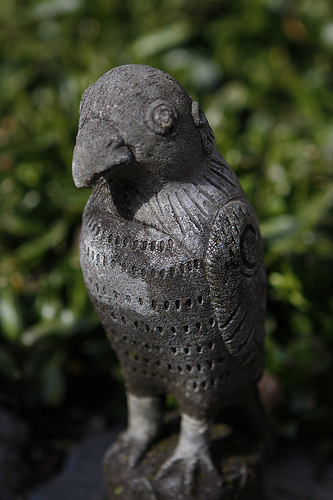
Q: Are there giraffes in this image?
A: No, there are no giraffes.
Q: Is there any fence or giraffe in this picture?
A: No, there are no giraffes or fences.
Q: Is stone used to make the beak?
A: Yes, the beak is made of stone.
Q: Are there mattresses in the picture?
A: No, there are no mattresses.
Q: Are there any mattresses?
A: No, there are no mattresses.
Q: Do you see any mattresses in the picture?
A: No, there are no mattresses.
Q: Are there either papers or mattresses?
A: No, there are no mattresses or papers.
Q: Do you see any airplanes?
A: No, there are no airplanes.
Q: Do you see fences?
A: No, there are no fences.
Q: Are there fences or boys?
A: No, there are no fences or boys.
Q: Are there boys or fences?
A: No, there are no fences or boys.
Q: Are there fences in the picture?
A: No, there are no fences.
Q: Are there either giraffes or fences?
A: No, there are no fences or giraffes.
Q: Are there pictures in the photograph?
A: No, there are no pictures.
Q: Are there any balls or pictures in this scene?
A: No, there are no pictures or balls.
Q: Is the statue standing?
A: Yes, the statue is standing.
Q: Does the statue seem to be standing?
A: Yes, the statue is standing.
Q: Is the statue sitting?
A: No, the statue is standing.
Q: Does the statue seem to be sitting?
A: No, the statue is standing.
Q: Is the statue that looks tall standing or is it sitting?
A: The statue is standing.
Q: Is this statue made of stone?
A: Yes, the statue is made of stone.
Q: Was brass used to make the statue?
A: No, the statue is made of stone.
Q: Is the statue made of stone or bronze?
A: The statue is made of stone.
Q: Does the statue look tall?
A: Yes, the statue is tall.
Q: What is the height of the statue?
A: The statue is tall.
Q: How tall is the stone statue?
A: The statue is tall.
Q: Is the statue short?
A: No, the statue is tall.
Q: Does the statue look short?
A: No, the statue is tall.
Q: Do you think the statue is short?
A: No, the statue is tall.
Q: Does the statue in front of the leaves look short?
A: No, the statue is tall.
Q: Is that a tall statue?
A: Yes, that is a tall statue.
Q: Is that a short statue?
A: No, that is a tall statue.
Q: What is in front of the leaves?
A: The statue is in front of the leaves.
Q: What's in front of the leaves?
A: The statue is in front of the leaves.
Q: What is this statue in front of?
A: The statue is in front of the leaves.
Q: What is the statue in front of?
A: The statue is in front of the leaves.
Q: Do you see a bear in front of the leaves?
A: No, there is a statue in front of the leaves.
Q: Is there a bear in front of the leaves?
A: No, there is a statue in front of the leaves.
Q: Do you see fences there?
A: No, there are no fences.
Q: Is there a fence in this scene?
A: No, there are no fences.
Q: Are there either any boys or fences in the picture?
A: No, there are no fences or boys.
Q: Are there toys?
A: No, there are no toys.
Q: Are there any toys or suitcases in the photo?
A: No, there are no toys or suitcases.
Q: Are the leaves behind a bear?
A: No, the leaves are behind the statue.